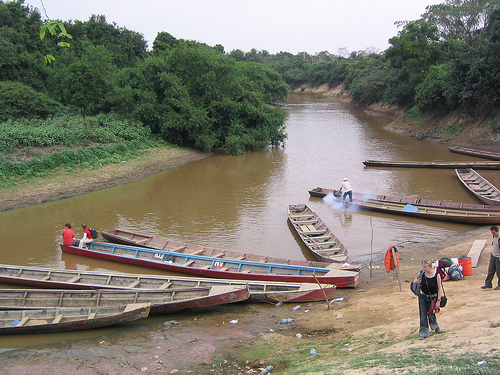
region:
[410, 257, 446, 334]
woman standing near the canoes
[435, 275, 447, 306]
black purse over woman's shoulder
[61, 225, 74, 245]
red shirt person is wearing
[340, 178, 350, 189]
white tee shirt man is wearing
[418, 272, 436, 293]
black tank top woman is wearing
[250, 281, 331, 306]
front of the red and white canoe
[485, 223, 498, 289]
man walking near the water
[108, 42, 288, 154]
bunch of trees next to the water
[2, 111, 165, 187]
small bushes next to the tall trees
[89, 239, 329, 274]
blue railing of the boat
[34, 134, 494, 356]
many boats in water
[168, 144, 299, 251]
water is brown and murky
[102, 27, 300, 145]
green tree encroaching into water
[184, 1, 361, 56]
sky is grey and cloudy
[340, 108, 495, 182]
brown dirt on hillside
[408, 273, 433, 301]
woman has black shirt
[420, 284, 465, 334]
woman has blue pants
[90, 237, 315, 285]
boat has blue frame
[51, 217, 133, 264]
people sit on end of boat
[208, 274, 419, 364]
bottles strewn on shore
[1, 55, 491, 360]
Canoes on the side of the riverbank.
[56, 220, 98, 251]
Two people wearing red shirts.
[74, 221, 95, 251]
A person wearing white pants.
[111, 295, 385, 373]
Trash is littering the ground.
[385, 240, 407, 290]
An orange jacket.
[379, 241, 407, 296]
Jacket hanging on a wooden post.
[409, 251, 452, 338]
A woman wearing a black top.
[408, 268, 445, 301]
A black tank top.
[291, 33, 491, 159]
Green trees and shrubs on the right side of the river.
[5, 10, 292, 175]
Green trees and shrubs on the left side of the river.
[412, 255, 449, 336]
blonde woman with black tank top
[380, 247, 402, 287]
bright orange puffy jacket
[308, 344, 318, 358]
blue plastic shopping bag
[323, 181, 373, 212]
boat engine surrounded in grey smoke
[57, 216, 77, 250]
man in bright orange t-shirt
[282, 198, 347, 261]
long grey wooden boat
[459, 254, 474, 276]
bright orange plastic bucket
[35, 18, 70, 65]
bright green leaves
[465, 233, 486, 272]
small wooden plank side walk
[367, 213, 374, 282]
tall skinny wooden stake in the ground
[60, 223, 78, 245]
Man wearing red on a boat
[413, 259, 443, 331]
A woman wearing black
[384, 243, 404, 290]
A jacket on a stake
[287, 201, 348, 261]
A boat in a river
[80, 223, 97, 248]
A girl sitting in a boat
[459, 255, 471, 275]
A full orange bucket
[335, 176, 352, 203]
Man pouring water in a river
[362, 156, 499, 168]
A long boat in a river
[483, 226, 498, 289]
A man wearing a gray shirt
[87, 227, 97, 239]
A blue backpack worn by a lady